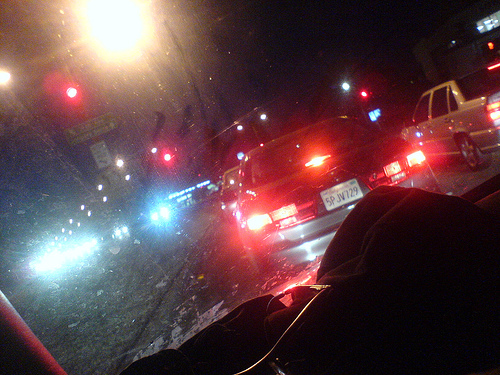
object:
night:
[1, 0, 500, 374]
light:
[66, 87, 77, 98]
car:
[234, 119, 442, 274]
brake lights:
[245, 149, 427, 234]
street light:
[361, 91, 368, 98]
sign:
[89, 140, 114, 169]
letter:
[63, 111, 120, 146]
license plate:
[319, 177, 364, 212]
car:
[400, 60, 500, 172]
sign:
[63, 111, 120, 148]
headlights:
[148, 207, 173, 227]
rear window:
[241, 118, 388, 192]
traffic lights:
[149, 147, 173, 162]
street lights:
[80, 159, 132, 217]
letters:
[325, 186, 360, 206]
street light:
[72, 0, 161, 66]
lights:
[236, 114, 267, 131]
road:
[119, 243, 215, 302]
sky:
[179, 0, 396, 65]